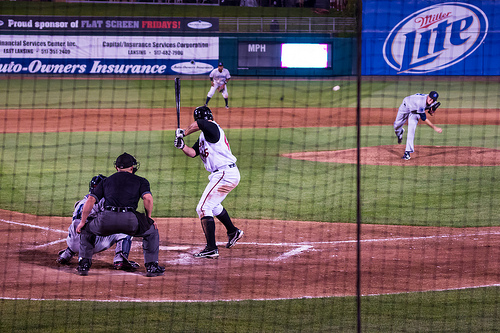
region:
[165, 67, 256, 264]
person playing baseball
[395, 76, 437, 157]
person playing baseball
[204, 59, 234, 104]
person playing baseball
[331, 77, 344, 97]
white baseball in mid air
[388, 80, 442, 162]
person is throwing a pitch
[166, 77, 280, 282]
person is holding a bat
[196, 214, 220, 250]
long sock on left leg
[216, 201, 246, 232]
long sock on right leg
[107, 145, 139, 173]
person wearing a face mask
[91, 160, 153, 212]
person wearing a black shirt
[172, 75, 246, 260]
a baseball player at bat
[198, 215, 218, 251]
a tall black sock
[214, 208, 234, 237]
a tall black sock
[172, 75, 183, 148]
a black baseball bat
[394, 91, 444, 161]
a baseball pitcher on mound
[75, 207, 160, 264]
a pair of grey pants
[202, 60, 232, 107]
a baseball player on field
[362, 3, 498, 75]
a Miller Lite stadium advertisement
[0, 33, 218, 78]
a stadium promotional advertisement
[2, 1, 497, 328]
a black protective netting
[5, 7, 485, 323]
Photo taken at a baseball game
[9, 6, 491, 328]
Photo taken at a baseball field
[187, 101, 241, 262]
The batter is left handed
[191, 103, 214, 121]
Helmet on the batter's head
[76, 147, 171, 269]
Umpire behind the catcher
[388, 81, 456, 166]
Pitcher on the mound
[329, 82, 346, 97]
Baseball in the air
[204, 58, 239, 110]
The player is a short stop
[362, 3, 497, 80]
Miller light ad in center field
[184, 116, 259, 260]
White uniform on the batter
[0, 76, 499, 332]
A baseball field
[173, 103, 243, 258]
A baseball player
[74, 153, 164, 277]
A umpire in a baseball game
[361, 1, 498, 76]
A blue Miller Lite sign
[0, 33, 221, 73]
A blue and white sign.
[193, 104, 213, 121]
A black protective helmet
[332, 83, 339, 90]
A baseball flying in the air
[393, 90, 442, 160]
A pitcher throwing a ball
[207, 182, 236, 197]
Red dirt on uniform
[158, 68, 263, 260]
Batter in white uniform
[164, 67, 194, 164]
Batter holding a black bat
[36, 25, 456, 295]
A black net behind batter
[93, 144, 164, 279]
The umpire behind the catcher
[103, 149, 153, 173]
A black cap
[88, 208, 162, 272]
A pair of grey pants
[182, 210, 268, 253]
Batter wearing black socks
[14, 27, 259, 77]
A long adverstisement sign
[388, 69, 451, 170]
Pitcher tossing a ball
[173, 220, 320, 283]
Dirt with white markings